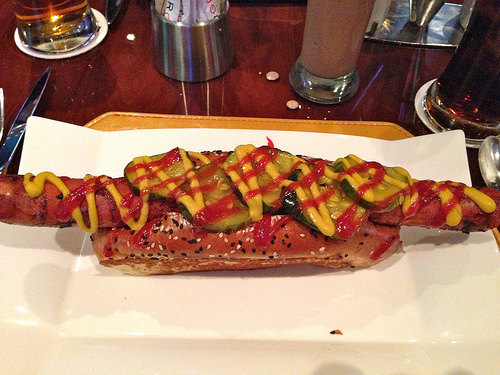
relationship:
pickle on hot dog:
[125, 150, 195, 201] [0, 172, 497, 234]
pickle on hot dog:
[179, 156, 254, 234] [0, 172, 497, 234]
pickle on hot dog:
[225, 149, 295, 215] [0, 172, 497, 234]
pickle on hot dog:
[286, 156, 369, 241] [0, 172, 497, 234]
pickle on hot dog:
[335, 154, 413, 211] [0, 172, 497, 234]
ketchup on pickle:
[128, 150, 178, 181] [125, 150, 195, 201]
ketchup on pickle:
[193, 193, 239, 228] [179, 156, 254, 234]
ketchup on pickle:
[233, 145, 275, 187] [225, 149, 295, 215]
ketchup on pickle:
[285, 156, 328, 201] [286, 156, 369, 241]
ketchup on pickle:
[342, 162, 384, 178] [335, 154, 413, 211]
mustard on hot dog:
[22, 144, 499, 237] [0, 172, 497, 234]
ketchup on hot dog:
[128, 150, 178, 181] [0, 172, 497, 234]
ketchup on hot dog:
[193, 193, 239, 228] [0, 172, 497, 234]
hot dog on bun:
[0, 172, 497, 234] [93, 212, 402, 276]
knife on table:
[1, 66, 52, 175] [0, 1, 499, 374]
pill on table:
[265, 70, 281, 81] [0, 1, 499, 374]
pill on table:
[283, 99, 300, 111] [0, 1, 499, 374]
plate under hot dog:
[1, 115, 499, 373] [0, 172, 497, 234]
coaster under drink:
[13, 8, 109, 60] [12, 0, 99, 55]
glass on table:
[288, 0, 380, 106] [0, 1, 499, 374]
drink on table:
[12, 0, 99, 55] [0, 1, 499, 374]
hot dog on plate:
[0, 172, 497, 234] [1, 115, 499, 373]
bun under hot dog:
[93, 212, 402, 276] [0, 172, 497, 234]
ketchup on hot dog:
[233, 145, 275, 187] [0, 172, 497, 234]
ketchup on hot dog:
[285, 156, 328, 201] [0, 172, 497, 234]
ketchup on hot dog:
[342, 162, 384, 178] [0, 172, 497, 234]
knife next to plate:
[1, 66, 52, 175] [1, 115, 499, 373]